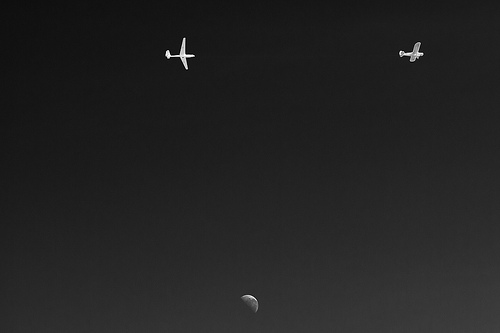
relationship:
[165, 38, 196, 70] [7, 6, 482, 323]
airplane flying in sky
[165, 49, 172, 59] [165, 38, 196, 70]
tail on airplane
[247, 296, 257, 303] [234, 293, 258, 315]
shadow on moon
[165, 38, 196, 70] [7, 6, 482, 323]
airplane in sky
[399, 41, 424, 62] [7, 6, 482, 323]
airplane in sky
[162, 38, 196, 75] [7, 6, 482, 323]
airplane in sky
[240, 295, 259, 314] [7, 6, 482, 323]
moon in sky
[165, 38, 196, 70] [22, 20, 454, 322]
airplane in sky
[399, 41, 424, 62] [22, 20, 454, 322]
airplane in sky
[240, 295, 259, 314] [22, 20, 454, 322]
moon in sky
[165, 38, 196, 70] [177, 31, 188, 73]
airplane with wings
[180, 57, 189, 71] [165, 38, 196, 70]
wing on airplane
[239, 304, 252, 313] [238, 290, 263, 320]
part of a moon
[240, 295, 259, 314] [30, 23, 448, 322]
moon in dark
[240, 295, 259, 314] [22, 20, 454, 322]
moon in a sky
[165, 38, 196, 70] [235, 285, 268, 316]
airplane flying over moon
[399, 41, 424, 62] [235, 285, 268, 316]
airplane flying over moon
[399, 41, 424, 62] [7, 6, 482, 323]
airplane flying in sky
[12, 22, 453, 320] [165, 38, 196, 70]
photo of airplane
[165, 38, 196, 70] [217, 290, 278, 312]
airplane over moon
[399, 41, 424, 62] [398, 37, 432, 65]
airplane flying at angle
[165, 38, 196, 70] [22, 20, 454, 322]
airplane flying straight in sky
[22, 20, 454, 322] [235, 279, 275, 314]
sky with moon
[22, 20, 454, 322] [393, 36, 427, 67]
sky with planes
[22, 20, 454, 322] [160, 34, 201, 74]
sky with planes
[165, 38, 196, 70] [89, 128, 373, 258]
airplane in sky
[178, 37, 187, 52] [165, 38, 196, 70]
wing on airplane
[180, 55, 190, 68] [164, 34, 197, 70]
wing on plane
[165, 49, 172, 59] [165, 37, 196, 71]
tail on plane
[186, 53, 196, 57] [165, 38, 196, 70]
nose on airplane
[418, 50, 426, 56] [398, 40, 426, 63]
nose on airplane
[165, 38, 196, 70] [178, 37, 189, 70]
airplane with wingspan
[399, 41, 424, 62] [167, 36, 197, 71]
airplane pulling glider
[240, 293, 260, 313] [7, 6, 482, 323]
moon floating in sky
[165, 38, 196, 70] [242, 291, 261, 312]
airplane flying by moon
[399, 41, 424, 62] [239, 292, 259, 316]
airplane flying by moon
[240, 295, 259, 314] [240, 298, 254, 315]
moon in shadow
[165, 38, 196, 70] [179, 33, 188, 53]
airplane with wing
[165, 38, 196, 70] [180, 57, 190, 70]
airplane with wing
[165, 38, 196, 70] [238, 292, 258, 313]
airplane flying over moon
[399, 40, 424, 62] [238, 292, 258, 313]
airplane flying over moon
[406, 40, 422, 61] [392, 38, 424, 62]
wings on plane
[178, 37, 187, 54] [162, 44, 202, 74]
wing on plane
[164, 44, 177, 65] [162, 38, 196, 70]
tail on plane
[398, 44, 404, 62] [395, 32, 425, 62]
tail on plane